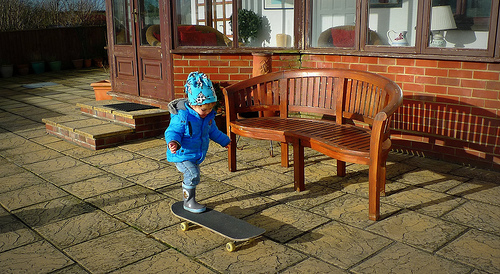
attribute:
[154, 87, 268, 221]
jacket — blue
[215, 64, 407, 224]
bench — wooden